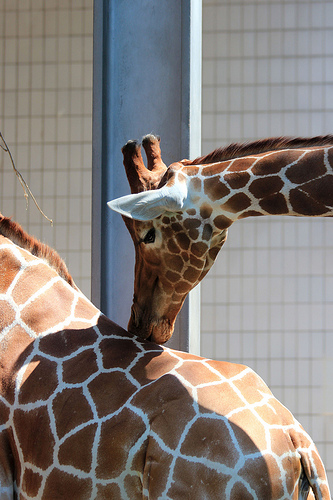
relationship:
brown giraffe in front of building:
[104, 131, 332, 345] [9, 56, 322, 416]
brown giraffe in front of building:
[1, 214, 332, 498] [9, 56, 322, 416]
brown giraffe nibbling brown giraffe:
[104, 131, 332, 345] [1, 214, 332, 498]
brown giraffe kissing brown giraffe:
[104, 131, 332, 345] [1, 214, 332, 498]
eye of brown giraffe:
[134, 222, 157, 249] [104, 131, 332, 345]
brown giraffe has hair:
[104, 131, 332, 345] [186, 132, 331, 166]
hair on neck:
[186, 132, 331, 166] [203, 137, 332, 226]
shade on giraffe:
[4, 314, 266, 498] [94, 111, 326, 334]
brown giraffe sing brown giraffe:
[104, 131, 332, 345] [1, 214, 332, 498]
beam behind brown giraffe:
[90, 0, 203, 357] [104, 131, 332, 345]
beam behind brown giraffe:
[90, 0, 203, 357] [1, 214, 332, 498]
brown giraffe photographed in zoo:
[104, 131, 332, 345] [3, 2, 328, 499]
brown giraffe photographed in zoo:
[1, 214, 332, 498] [3, 2, 328, 499]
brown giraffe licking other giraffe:
[104, 131, 332, 345] [18, 242, 271, 472]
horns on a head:
[118, 129, 166, 184] [102, 118, 232, 338]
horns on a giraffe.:
[118, 129, 166, 184] [108, 120, 328, 359]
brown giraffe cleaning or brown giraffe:
[104, 131, 332, 345] [1, 214, 332, 498]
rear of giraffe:
[150, 344, 317, 498] [63, 116, 329, 350]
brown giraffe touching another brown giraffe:
[104, 131, 332, 345] [1, 214, 332, 498]